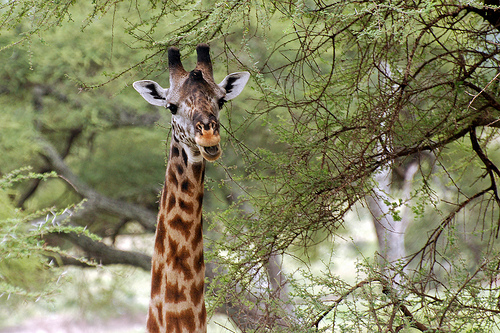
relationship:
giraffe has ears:
[158, 44, 261, 331] [138, 45, 258, 105]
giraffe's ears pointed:
[163, 72, 260, 255] [216, 53, 262, 125]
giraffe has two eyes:
[158, 44, 261, 331] [162, 82, 247, 120]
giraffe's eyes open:
[163, 72, 260, 255] [168, 86, 201, 125]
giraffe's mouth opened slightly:
[163, 72, 260, 255] [197, 128, 233, 167]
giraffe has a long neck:
[158, 44, 261, 331] [138, 123, 219, 332]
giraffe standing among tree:
[158, 44, 261, 331] [361, 32, 469, 123]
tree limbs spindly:
[321, 36, 478, 186] [272, 34, 372, 145]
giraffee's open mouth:
[162, 54, 223, 236] [197, 128, 233, 167]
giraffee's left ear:
[162, 54, 223, 236] [218, 64, 263, 101]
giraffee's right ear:
[162, 54, 223, 236] [218, 64, 263, 101]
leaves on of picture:
[242, 39, 342, 80] [374, 11, 499, 55]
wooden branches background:
[60, 182, 121, 279] [97, 103, 121, 130]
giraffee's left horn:
[162, 54, 223, 236] [154, 39, 218, 75]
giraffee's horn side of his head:
[162, 54, 223, 236] [157, 71, 196, 149]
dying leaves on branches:
[265, 114, 310, 175] [325, 91, 426, 207]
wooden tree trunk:
[60, 182, 121, 279] [57, 212, 115, 269]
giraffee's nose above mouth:
[162, 54, 223, 236] [182, 118, 214, 141]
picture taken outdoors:
[7, 17, 444, 282] [227, 42, 384, 155]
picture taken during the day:
[7, 17, 444, 282] [238, 42, 327, 103]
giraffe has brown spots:
[158, 44, 261, 331] [160, 179, 187, 230]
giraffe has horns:
[158, 44, 261, 331] [154, 39, 218, 75]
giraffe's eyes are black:
[163, 72, 260, 255] [154, 101, 178, 122]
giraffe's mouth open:
[163, 72, 260, 255] [168, 86, 201, 125]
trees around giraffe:
[321, 36, 478, 186] [158, 44, 261, 331]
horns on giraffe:
[164, 28, 238, 72] [158, 44, 261, 331]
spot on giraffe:
[166, 217, 189, 234] [158, 44, 261, 331]